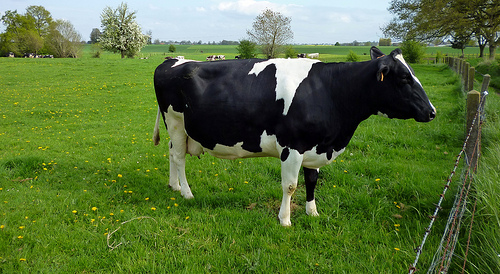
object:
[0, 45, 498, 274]
field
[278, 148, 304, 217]
legs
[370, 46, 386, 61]
ear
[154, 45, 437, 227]
cow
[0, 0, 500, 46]
sky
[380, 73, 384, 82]
tag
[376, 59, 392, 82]
ear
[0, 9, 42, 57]
trees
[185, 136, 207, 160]
udder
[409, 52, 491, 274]
barbed wire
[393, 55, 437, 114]
line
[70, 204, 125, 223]
dandelions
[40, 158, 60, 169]
dandelions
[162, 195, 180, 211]
dandelions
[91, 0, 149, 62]
tree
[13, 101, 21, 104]
flowers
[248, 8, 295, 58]
tree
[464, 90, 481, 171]
post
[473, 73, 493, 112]
post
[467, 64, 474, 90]
post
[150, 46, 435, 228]
hide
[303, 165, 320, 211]
leg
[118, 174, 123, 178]
blooms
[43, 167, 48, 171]
blooms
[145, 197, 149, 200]
blooms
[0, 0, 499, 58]
background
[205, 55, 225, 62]
cows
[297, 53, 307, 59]
cows